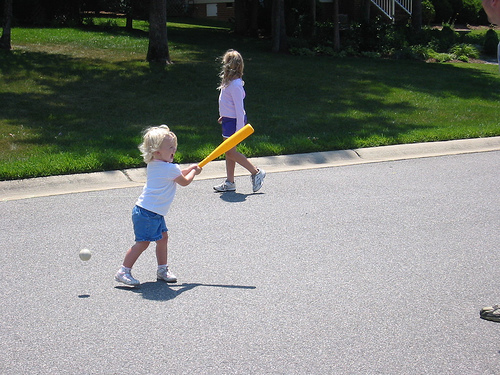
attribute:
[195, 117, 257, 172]
bat — yellow, plastic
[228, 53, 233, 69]
hair — blowing, blond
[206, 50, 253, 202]
girl — walking, turned, young, blonde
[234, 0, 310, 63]
trees — background, tall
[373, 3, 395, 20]
rail — white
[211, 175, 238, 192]
shoe — tennis, white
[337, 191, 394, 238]
road — paved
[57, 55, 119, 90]
lawn — background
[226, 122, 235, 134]
shorts — blue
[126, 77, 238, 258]
kids — playing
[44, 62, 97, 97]
grass — green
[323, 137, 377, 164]
curb — white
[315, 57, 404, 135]
yard — green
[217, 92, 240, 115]
shirt — white, pink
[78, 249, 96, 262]
ball — white